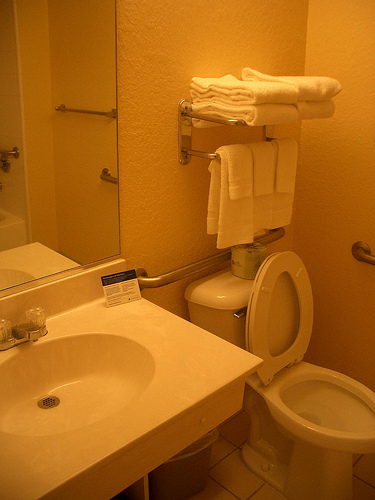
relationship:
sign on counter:
[95, 268, 143, 310] [2, 291, 263, 498]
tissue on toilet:
[233, 242, 268, 280] [181, 250, 373, 499]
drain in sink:
[41, 392, 61, 409] [0, 332, 156, 443]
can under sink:
[149, 434, 219, 495] [0, 332, 156, 443]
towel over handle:
[188, 73, 300, 111] [134, 225, 288, 290]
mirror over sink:
[2, 0, 123, 295] [0, 332, 156, 443]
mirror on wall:
[2, 0, 123, 295] [0, 0, 311, 332]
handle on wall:
[134, 225, 288, 290] [0, 0, 311, 332]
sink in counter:
[0, 332, 156, 443] [2, 291, 263, 498]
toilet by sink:
[181, 250, 373, 499] [0, 332, 156, 443]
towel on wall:
[188, 73, 300, 111] [0, 0, 311, 332]